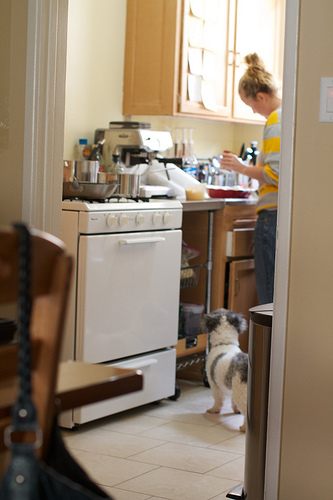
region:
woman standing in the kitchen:
[217, 53, 281, 302]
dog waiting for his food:
[201, 307, 248, 431]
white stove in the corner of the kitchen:
[61, 199, 182, 424]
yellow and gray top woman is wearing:
[256, 103, 281, 211]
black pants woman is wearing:
[252, 208, 277, 305]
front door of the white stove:
[74, 229, 181, 363]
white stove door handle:
[118, 235, 165, 243]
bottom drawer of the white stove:
[71, 346, 175, 424]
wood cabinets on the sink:
[123, 0, 277, 127]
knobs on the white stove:
[103, 212, 172, 227]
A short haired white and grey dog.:
[200, 307, 249, 431]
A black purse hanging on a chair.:
[1, 218, 115, 499]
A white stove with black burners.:
[55, 195, 182, 428]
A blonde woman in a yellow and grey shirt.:
[219, 51, 282, 307]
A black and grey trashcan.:
[228, 302, 274, 498]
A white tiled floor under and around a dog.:
[61, 384, 247, 498]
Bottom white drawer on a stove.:
[73, 346, 178, 425]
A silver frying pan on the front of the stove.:
[63, 176, 119, 198]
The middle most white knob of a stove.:
[135, 212, 146, 225]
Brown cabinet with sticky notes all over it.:
[127, 1, 233, 119]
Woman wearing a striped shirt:
[229, 51, 276, 306]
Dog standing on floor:
[199, 304, 252, 433]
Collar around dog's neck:
[209, 338, 239, 352]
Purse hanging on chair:
[5, 213, 112, 499]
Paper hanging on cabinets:
[186, 0, 229, 114]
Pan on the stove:
[60, 174, 117, 202]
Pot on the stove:
[98, 163, 180, 201]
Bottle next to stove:
[71, 135, 92, 162]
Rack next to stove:
[167, 197, 227, 403]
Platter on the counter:
[203, 181, 254, 201]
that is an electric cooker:
[76, 207, 183, 388]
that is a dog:
[203, 305, 245, 416]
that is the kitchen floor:
[147, 437, 174, 495]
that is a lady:
[233, 64, 286, 306]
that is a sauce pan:
[40, 176, 112, 199]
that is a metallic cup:
[121, 175, 138, 190]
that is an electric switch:
[315, 82, 329, 122]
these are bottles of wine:
[239, 138, 264, 161]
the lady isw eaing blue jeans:
[246, 216, 272, 288]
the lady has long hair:
[241, 46, 278, 99]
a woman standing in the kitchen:
[221, 49, 279, 303]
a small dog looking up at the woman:
[198, 306, 251, 432]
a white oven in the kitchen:
[57, 199, 185, 430]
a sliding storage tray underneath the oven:
[70, 344, 183, 425]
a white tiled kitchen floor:
[51, 377, 248, 498]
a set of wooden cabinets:
[123, 0, 283, 122]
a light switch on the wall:
[319, 77, 332, 120]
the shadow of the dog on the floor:
[168, 403, 247, 443]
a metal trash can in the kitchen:
[223, 299, 275, 498]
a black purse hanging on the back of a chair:
[0, 220, 116, 499]